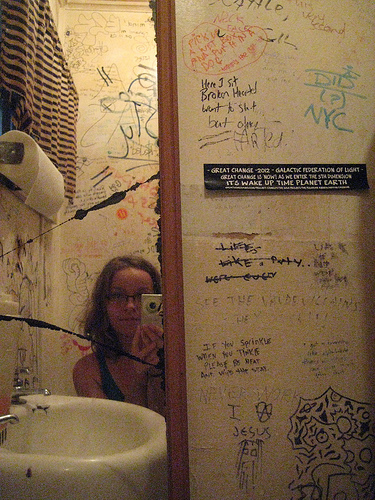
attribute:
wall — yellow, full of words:
[8, 0, 365, 390]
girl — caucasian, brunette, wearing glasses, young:
[72, 254, 165, 419]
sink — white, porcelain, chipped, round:
[7, 411, 193, 484]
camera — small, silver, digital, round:
[126, 277, 188, 353]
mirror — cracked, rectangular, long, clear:
[10, 11, 177, 489]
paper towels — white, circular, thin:
[2, 125, 67, 223]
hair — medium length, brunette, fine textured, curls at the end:
[84, 260, 116, 354]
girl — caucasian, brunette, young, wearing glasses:
[73, 252, 173, 421]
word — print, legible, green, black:
[201, 78, 217, 89]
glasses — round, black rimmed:
[106, 288, 153, 305]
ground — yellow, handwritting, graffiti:
[267, 60, 293, 84]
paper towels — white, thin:
[1, 129, 68, 218]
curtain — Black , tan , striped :
[9, 63, 51, 129]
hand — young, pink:
[128, 329, 153, 372]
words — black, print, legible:
[198, 76, 285, 149]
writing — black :
[227, 401, 273, 495]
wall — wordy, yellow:
[175, 0, 374, 498]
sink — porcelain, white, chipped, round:
[1, 364, 170, 497]